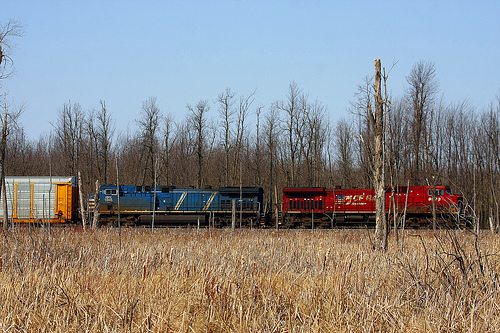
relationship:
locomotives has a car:
[1, 175, 467, 230] [0, 175, 80, 226]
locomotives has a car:
[1, 175, 467, 230] [89, 183, 264, 224]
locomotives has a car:
[1, 175, 467, 230] [280, 185, 465, 229]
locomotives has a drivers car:
[1, 175, 467, 230] [280, 185, 465, 229]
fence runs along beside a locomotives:
[2, 207, 498, 232] [1, 175, 467, 230]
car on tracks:
[0, 175, 80, 226] [3, 223, 495, 230]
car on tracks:
[89, 183, 264, 224] [3, 223, 495, 230]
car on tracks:
[280, 185, 465, 229] [3, 223, 495, 230]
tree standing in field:
[368, 57, 388, 251] [1, 225, 498, 332]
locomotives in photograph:
[1, 175, 467, 230] [1, 1, 499, 331]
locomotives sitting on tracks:
[1, 175, 467, 230] [3, 223, 495, 230]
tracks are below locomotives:
[3, 223, 495, 230] [1, 175, 467, 230]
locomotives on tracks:
[1, 175, 467, 230] [3, 223, 495, 230]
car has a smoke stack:
[280, 185, 465, 229] [335, 184, 341, 192]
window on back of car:
[104, 186, 112, 196] [89, 183, 264, 224]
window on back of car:
[110, 189, 116, 195] [89, 183, 264, 224]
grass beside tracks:
[1, 225, 498, 331] [3, 223, 495, 230]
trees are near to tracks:
[1, 85, 498, 236] [3, 223, 495, 230]